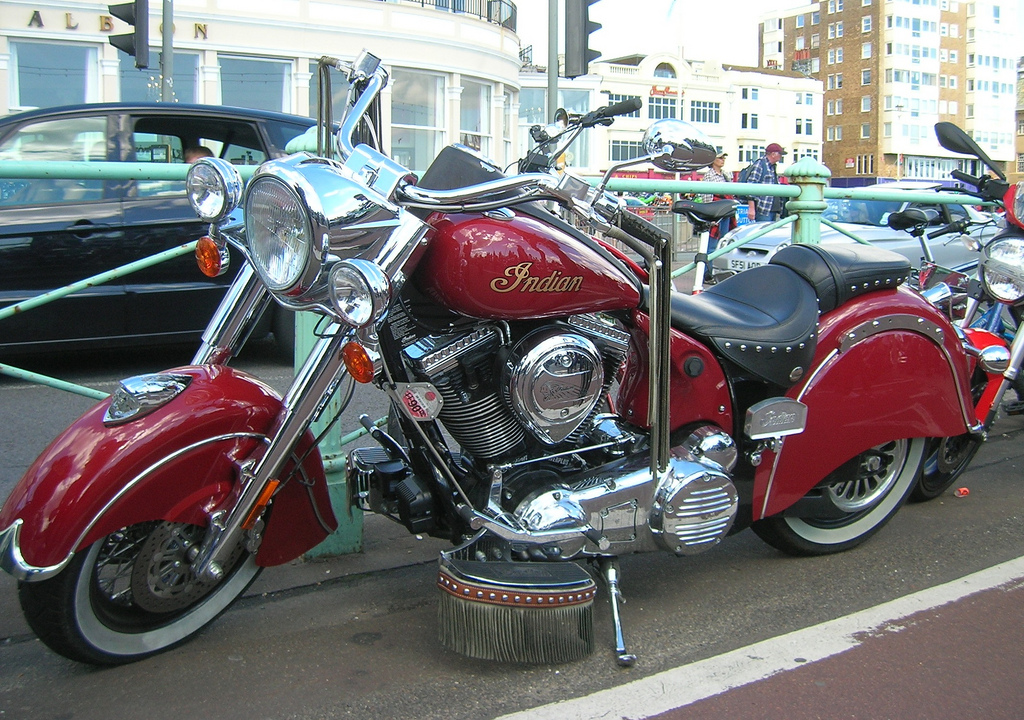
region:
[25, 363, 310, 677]
Front wheelon a motorcycle.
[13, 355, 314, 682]
Black, white and red wheel and wheel cover.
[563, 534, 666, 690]
Kick stand on a motorcycle.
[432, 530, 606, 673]
Foot rest on a motorcycle.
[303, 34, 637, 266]
Handle bar on a motorcycle.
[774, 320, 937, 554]
Back wheel on a motorcycle.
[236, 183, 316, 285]
Large light on front of bike.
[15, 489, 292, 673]
Black tire on front of bike.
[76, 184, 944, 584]
Red bike parked on side of street.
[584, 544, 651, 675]
Bike has silver kick stand.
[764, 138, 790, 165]
Person wearing red baseball cap.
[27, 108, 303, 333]
Black car on side of road.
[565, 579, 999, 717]
White line marking pavement.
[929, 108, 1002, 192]
Black mirror on side of bike.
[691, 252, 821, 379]
Black seat on bike.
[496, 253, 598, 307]
gold letters on a red motorcycle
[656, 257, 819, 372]
a black seat on a motorcycle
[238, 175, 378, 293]
a chrome headlight on a motorcycle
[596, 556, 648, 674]
a chrome kickstand on a motorcycle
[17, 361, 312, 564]
a red fender on a motorcycle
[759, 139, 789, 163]
a man wearing a red hat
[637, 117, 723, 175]
a chrome rear view mirror on a motorcycle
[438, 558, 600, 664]
a foot rest on a motorcycle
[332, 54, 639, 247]
chrome handle bars on a motorcycle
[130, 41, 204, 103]
window on the building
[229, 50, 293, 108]
window on the building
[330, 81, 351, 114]
window on the building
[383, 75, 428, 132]
window on the building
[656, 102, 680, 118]
window on the building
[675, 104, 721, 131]
window on the building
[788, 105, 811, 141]
window on the building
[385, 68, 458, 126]
building has a window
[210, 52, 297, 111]
building has a window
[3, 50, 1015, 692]
red bike on the side of the road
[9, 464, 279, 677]
front tire of the bike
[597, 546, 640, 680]
kickstand of the bike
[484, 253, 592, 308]
logo on the bike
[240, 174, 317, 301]
large headlight on the bike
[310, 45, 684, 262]
handlebars of the bikes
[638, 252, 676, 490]
tassels on the bike's handlebars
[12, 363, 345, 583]
front fender of the bike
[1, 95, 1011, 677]
The bike is red.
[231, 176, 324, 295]
The light is off.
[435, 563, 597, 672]
part of a motorcycle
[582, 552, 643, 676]
part of a motorcycle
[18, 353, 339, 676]
part of a motorcycle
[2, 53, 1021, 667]
the motorcycle is dark red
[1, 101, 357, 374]
the car is black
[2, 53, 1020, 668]
the motorcycles are parked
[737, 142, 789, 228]
the man is wearing a hat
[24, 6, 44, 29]
the letter A is gold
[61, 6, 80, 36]
the letter L is gold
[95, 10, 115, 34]
the letter B is gold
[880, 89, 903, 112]
window on the building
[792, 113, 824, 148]
window on the building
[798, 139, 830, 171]
window on the building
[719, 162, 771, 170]
window on the building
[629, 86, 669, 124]
window on the building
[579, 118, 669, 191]
window on the building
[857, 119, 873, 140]
A window on a building.